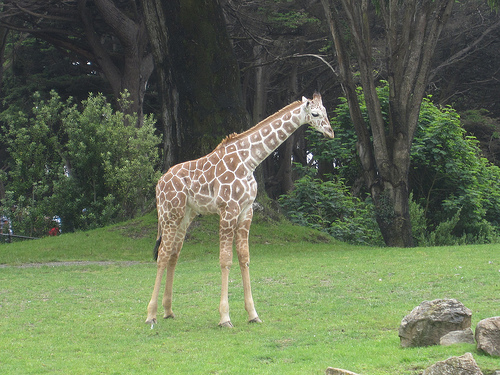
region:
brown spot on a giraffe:
[220, 166, 232, 178]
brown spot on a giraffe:
[170, 195, 181, 205]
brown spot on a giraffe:
[245, 130, 265, 140]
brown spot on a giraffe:
[260, 126, 270, 131]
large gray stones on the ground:
[395, 289, 493, 371]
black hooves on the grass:
[216, 318, 266, 330]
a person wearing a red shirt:
[44, 218, 61, 236]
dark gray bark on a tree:
[361, 137, 409, 241]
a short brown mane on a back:
[225, 130, 240, 142]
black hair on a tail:
[151, 237, 161, 262]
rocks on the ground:
[386, 286, 470, 348]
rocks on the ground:
[378, 265, 495, 370]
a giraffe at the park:
[109, 95, 364, 372]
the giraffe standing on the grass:
[146, 90, 334, 327]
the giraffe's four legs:
[148, 210, 261, 330]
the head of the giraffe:
[304, 91, 334, 141]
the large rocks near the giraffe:
[399, 295, 499, 372]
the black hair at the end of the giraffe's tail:
[153, 239, 161, 261]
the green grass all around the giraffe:
[1, 205, 498, 373]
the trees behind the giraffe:
[1, 1, 498, 249]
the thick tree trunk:
[139, 1, 267, 198]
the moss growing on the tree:
[175, 19, 225, 137]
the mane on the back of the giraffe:
[215, 99, 304, 151]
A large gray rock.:
[398, 297, 474, 350]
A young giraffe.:
[138, 90, 335, 330]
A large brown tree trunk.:
[314, 1, 452, 248]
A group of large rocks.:
[399, 296, 499, 373]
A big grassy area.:
[2, 211, 497, 373]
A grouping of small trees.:
[0, 86, 172, 244]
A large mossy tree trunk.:
[141, 2, 272, 204]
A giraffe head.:
[298, 88, 335, 142]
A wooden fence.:
[0, 231, 42, 243]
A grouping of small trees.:
[276, 79, 498, 244]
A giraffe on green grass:
[127, 88, 349, 326]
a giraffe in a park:
[114, 87, 342, 319]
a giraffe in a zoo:
[117, 80, 349, 344]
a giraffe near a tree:
[138, 61, 343, 352]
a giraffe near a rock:
[128, 74, 469, 355]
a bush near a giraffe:
[7, 94, 335, 318]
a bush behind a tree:
[322, 81, 497, 223]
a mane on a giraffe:
[198, 94, 309, 159]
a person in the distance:
[40, 210, 64, 237]